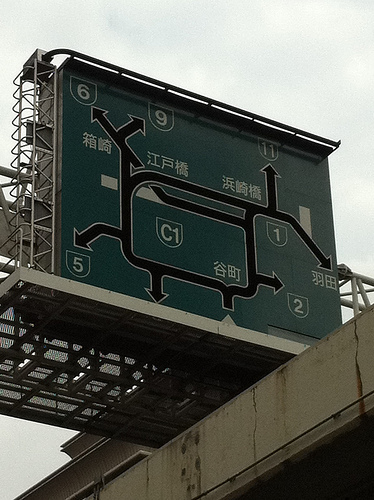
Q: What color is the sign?
A: The sign is green.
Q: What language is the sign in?
A: The sign is in chinese.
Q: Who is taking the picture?
A: A photographer.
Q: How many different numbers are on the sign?
A: 6 different numbers.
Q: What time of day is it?
A: Day time.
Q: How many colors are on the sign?
A: 3 colors on the sign.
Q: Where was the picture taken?
A: Near overpass.